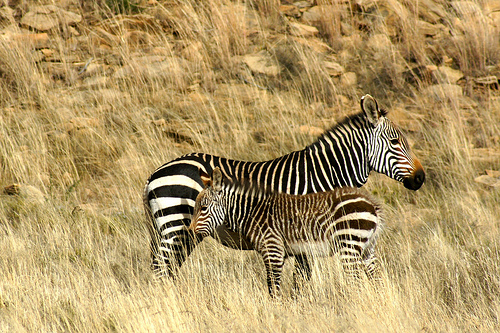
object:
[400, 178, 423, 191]
mouth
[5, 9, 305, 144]
tall grass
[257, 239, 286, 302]
front leg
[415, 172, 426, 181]
nose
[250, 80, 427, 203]
corner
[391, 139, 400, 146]
eye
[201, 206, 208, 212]
eye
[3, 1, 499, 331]
plantation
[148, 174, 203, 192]
stripes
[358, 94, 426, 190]
zebra head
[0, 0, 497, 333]
background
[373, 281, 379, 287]
tip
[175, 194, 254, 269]
shadow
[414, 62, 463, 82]
rocks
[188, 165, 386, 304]
animal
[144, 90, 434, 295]
clouds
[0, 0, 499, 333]
field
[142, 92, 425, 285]
adult zebra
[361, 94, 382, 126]
ear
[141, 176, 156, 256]
tail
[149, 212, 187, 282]
leg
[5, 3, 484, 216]
slope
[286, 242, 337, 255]
patch